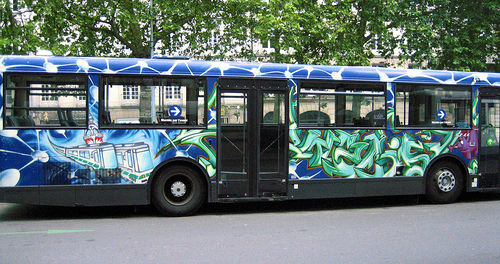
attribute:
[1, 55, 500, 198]
bus — long, blue, painted, big, parked, large, white, on road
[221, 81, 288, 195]
doors — black, open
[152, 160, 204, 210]
tire — black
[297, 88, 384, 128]
window — clear, glass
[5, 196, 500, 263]
road — grey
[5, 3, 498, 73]
trees — green, branched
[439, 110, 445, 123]
arrow — blue, white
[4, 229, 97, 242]
arrow — green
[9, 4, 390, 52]
leaves — green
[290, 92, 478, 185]
graffiti — green, light green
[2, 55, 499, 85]
roof — blue, white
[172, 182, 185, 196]
hubcap — small, white, circular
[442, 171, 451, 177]
dots — dark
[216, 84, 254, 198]
back door — black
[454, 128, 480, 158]
image — purple, white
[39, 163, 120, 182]
lines — black